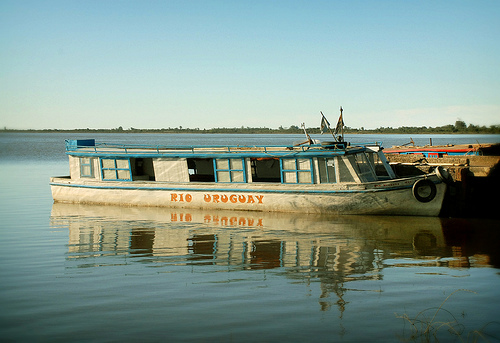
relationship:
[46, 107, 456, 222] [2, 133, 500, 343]
boat floating on water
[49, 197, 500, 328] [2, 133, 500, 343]
reflection in water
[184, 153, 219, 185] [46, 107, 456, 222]
window on side of boat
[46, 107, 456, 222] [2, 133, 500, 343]
boat floating in water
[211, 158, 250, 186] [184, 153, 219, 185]
pane in window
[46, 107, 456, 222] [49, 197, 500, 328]
boat has reflection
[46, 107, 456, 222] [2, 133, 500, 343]
boat sits in water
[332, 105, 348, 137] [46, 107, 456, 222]
flag on top of boat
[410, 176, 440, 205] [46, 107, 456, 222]
life preserver on side of boat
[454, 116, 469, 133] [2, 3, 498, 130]
tree in sky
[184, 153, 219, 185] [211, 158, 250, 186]
window has pane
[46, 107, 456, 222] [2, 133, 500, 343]
boat on body of water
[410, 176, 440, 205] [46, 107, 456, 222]
life preserver in front of boat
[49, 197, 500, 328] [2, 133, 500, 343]
reflection on top of water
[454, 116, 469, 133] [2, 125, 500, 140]
tree on shore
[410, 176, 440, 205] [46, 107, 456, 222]
life preserver on nose of boat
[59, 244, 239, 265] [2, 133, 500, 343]
ripple formed in water